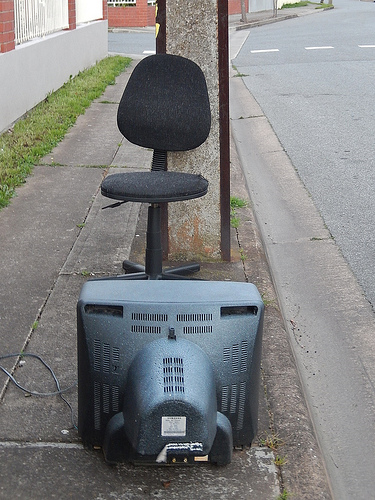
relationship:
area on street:
[137, 37, 369, 56] [250, 26, 372, 274]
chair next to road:
[101, 51, 214, 279] [218, 0, 373, 496]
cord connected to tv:
[1, 347, 74, 437] [72, 280, 263, 473]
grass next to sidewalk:
[0, 52, 130, 204] [9, 55, 183, 361]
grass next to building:
[0, 52, 130, 204] [1, 1, 110, 128]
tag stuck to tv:
[160, 417, 186, 437] [72, 280, 263, 473]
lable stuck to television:
[160, 415, 185, 435] [79, 270, 267, 467]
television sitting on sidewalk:
[72, 278, 262, 468] [1, 58, 299, 495]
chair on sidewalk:
[101, 51, 214, 279] [1, 58, 299, 495]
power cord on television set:
[1, 348, 66, 430] [68, 278, 271, 468]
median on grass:
[2, 45, 129, 204] [0, 52, 130, 204]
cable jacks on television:
[165, 443, 205, 466] [78, 284, 248, 459]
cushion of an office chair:
[110, 63, 258, 182] [77, 49, 230, 286]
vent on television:
[170, 308, 225, 326] [72, 278, 262, 468]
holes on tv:
[132, 307, 214, 334] [72, 280, 263, 473]